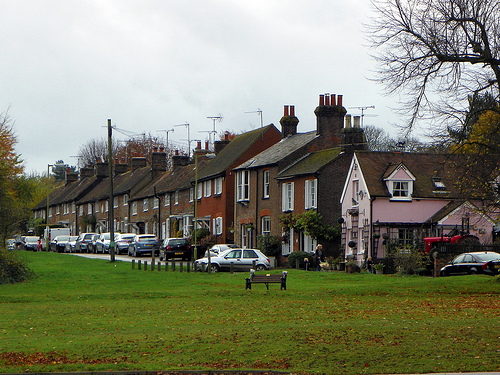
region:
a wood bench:
[222, 269, 297, 301]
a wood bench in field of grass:
[127, 258, 314, 343]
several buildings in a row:
[52, 114, 339, 244]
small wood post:
[132, 259, 216, 274]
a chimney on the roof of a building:
[310, 80, 364, 151]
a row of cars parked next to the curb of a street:
[70, 224, 196, 274]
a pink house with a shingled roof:
[356, 146, 437, 252]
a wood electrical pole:
[87, 106, 124, 276]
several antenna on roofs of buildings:
[141, 103, 268, 163]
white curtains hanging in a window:
[389, 171, 413, 202]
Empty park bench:
[234, 263, 296, 297]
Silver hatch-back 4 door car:
[191, 242, 278, 274]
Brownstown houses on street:
[23, 91, 334, 266]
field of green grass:
[35, 250, 495, 370]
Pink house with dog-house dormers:
[330, 130, 496, 280]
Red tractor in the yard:
[405, 201, 487, 261]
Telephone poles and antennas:
[40, 110, 395, 156]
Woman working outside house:
[292, 230, 347, 273]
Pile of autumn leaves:
[2, 347, 123, 368]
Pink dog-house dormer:
[380, 157, 422, 207]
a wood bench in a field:
[235, 265, 302, 307]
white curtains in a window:
[382, 162, 420, 209]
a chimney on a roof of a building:
[309, 77, 354, 160]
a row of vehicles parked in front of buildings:
[35, 228, 181, 264]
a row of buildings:
[32, 124, 352, 251]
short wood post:
[130, 259, 204, 279]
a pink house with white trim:
[336, 147, 448, 273]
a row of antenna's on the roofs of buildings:
[145, 97, 282, 157]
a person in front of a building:
[310, 236, 340, 276]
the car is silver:
[213, 242, 279, 274]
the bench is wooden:
[240, 262, 293, 289]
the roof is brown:
[361, 150, 461, 199]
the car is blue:
[159, 238, 191, 264]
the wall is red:
[198, 200, 229, 219]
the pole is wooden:
[100, 130, 125, 264]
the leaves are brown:
[363, 285, 467, 342]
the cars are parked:
[25, 223, 178, 258]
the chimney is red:
[314, 90, 347, 105]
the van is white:
[40, 223, 69, 233]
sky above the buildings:
[68, 18, 208, 81]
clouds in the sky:
[62, 14, 207, 100]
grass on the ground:
[117, 282, 204, 324]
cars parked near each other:
[54, 227, 194, 279]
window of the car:
[221, 245, 247, 265]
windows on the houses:
[209, 163, 279, 218]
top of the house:
[234, 117, 314, 184]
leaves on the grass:
[326, 275, 457, 363]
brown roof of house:
[407, 147, 457, 190]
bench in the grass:
[235, 265, 297, 304]